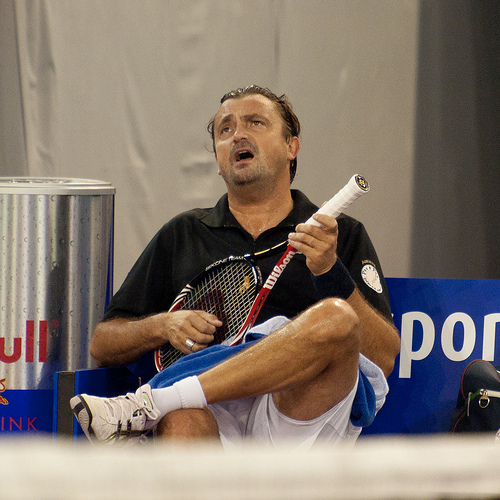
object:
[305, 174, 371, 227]
white handle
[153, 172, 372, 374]
racket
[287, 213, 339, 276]
hands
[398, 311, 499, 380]
advertising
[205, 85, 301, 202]
head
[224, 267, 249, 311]
net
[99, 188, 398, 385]
shirt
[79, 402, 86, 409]
black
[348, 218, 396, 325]
sleeve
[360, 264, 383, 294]
circle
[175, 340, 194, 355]
finger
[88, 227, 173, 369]
arm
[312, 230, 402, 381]
arm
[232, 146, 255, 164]
mouth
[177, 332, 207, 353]
finger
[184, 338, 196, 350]
ring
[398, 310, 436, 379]
letter p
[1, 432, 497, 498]
bench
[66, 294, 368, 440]
crossed legs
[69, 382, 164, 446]
white sneakers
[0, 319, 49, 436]
logo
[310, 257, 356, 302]
sweatband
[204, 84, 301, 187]
hair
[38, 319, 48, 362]
red l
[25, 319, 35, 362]
red l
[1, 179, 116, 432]
can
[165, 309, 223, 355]
hand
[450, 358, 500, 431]
bag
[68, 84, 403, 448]
guy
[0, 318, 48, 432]
advertisement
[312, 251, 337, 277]
wrist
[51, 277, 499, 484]
bench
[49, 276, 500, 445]
chair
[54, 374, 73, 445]
ink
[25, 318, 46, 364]
part